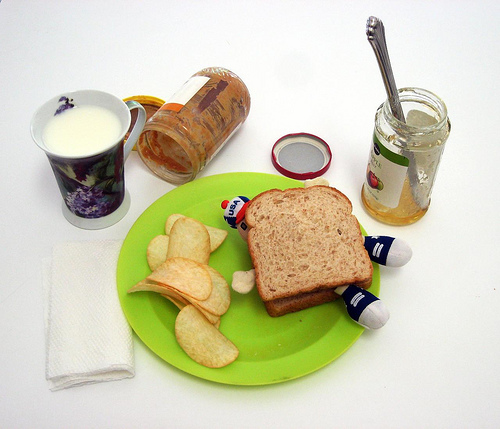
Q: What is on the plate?
A: A sandwich.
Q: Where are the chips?
A: On the plate.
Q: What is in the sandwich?
A: A doll.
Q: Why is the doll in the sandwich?
A: To eat.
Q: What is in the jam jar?
A: Knife.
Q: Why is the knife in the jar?
A: To scrape jam.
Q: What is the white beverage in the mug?
A: Milk.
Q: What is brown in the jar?
A: Peanut butter?.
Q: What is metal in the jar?
A: Butter knife.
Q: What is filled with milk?
A: The mug.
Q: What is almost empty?
A: The peanut butter can.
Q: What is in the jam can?
A: The knife.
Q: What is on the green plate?
A: Chips.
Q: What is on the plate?
A: Bread.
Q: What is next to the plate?
A: The napkin.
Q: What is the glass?
A: Empty.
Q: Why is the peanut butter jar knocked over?
A: The jar fell.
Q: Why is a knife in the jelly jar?
A: To spread it on the sandwich.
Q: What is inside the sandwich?
A: A stuffed toy.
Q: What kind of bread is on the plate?
A: Wheat bread.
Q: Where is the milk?
A: In the coffee cup.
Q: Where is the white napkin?
A: Under the plate.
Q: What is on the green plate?
A: A sandwich and chips.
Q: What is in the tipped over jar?
A: Peanut butter.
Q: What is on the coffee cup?
A: A purple flower.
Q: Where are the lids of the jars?
A: Laying on the table.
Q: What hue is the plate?
A: Green.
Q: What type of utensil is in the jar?
A: Knife.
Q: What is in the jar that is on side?
A: Peanut butter.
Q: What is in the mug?
A: Milk.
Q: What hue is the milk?
A: White.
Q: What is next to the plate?
A: Napkin.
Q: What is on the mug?
A: Purple flowers.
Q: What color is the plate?
A: Green.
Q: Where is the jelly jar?
A: To the right of the plate.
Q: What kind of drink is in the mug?
A: Milk.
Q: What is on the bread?
A: A stuffed man.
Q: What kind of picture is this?
A: Allegory.